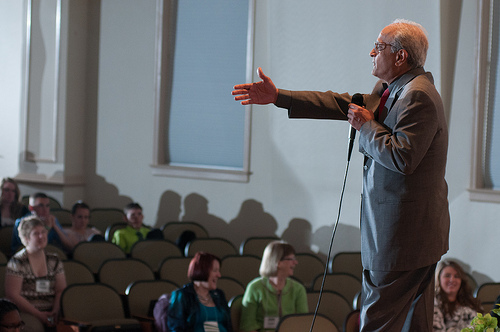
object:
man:
[228, 16, 449, 332]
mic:
[347, 91, 364, 165]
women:
[237, 239, 310, 331]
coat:
[360, 66, 448, 273]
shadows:
[151, 188, 186, 230]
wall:
[86, 0, 499, 299]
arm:
[277, 88, 354, 120]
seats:
[70, 240, 128, 281]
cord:
[306, 160, 352, 331]